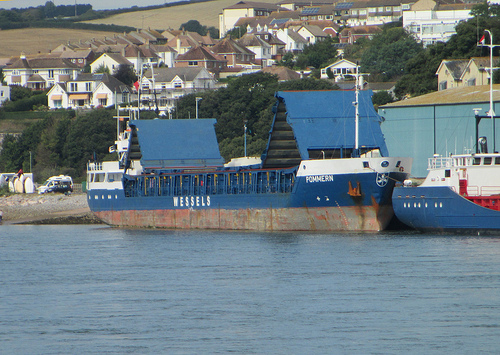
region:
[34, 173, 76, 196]
Black sedan and white van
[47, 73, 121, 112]
House with brown overhangs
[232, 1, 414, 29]
Building with sky light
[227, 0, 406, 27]
Building with solar panels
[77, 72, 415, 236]
Large cargo ship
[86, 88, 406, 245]
Large blue cargo ship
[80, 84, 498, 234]
Blue cargo ship pulling smaller boat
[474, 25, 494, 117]
Red and white flag on pole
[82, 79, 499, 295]
Cargo ship and boat on the water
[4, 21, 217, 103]
Man houses and apartments with brown and grey roofs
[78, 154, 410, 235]
a large blue and white boat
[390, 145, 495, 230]
a large blue red and white boat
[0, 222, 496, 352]
a large body of water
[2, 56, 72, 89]
large building in distance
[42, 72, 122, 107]
large building in distance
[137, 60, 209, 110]
large building in distance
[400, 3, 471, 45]
large building in distance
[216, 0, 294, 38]
large building in distance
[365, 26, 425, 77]
large green tree in distance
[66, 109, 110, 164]
large green tree in distance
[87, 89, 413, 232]
the big boat on the water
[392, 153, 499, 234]
the smaller boat on the water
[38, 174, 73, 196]
the parked cars on land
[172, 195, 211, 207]
the word WESSELS on the boat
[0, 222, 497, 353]
the body of water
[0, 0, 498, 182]
the trees on land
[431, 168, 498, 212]
the red coloring on the boat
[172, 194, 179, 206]
the letter "W" on the boat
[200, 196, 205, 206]
the letter "L" on the boat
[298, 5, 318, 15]
the solar panel on the roof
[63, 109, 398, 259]
ship has wessels written on side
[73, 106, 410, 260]
ship is blue and white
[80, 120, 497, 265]
two boats next to each other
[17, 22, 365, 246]
trees in between water and houses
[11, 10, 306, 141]
houses have brown roofs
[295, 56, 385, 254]
ship has white pole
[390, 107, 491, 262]
ship is blue, white and red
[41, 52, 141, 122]
house is multiple stories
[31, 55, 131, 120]
multiple story house is white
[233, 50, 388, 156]
building has blue roof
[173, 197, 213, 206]
The writing on the ship is white.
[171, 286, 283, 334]
The water is blue in color.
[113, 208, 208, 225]
The bottom on the ship is rusted.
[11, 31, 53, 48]
The hill in the background is brown.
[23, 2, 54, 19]
The trees in the background are green.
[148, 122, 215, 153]
The top of the ship is blue.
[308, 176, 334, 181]
The writing on the ship is white.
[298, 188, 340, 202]
The side of the ship is blue.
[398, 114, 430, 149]
The side of the building is green.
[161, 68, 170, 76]
The roof of the house is brown.